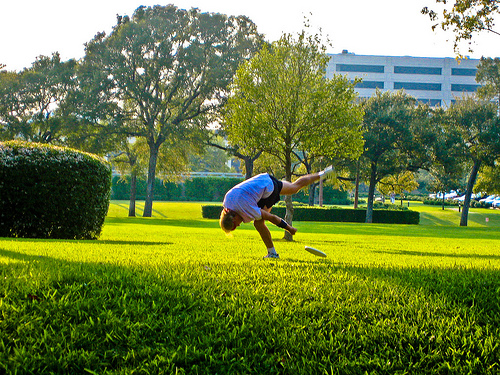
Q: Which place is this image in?
A: It is at the field.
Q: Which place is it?
A: It is a field.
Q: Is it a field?
A: Yes, it is a field.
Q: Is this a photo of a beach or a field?
A: It is showing a field.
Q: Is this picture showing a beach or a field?
A: It is showing a field.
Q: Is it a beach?
A: No, it is a field.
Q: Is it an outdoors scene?
A: Yes, it is outdoors.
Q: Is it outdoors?
A: Yes, it is outdoors.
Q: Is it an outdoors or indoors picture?
A: It is outdoors.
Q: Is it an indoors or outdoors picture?
A: It is outdoors.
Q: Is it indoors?
A: No, it is outdoors.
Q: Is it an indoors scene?
A: No, it is outdoors.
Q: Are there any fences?
A: No, there are no fences.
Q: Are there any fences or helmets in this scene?
A: No, there are no fences or helmets.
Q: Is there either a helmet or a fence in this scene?
A: No, there are no fences or helmets.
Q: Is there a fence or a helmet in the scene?
A: No, there are no fences or helmets.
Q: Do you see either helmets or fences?
A: No, there are no fences or helmets.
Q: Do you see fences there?
A: No, there are no fences.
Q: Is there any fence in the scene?
A: No, there are no fences.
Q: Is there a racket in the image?
A: No, there are no rackets.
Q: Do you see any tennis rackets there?
A: No, there are no tennis rackets.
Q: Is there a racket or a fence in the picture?
A: No, there are no rackets or fences.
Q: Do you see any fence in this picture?
A: No, there are no fences.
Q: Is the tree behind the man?
A: Yes, the tree is behind the man.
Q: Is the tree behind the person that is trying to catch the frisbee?
A: Yes, the tree is behind the man.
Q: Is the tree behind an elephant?
A: No, the tree is behind the man.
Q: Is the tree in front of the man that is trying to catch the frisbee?
A: No, the tree is behind the man.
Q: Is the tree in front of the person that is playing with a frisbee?
A: No, the tree is behind the man.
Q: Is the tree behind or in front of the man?
A: The tree is behind the man.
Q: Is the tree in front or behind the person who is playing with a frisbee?
A: The tree is behind the man.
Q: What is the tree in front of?
A: The tree is in front of the building.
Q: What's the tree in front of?
A: The tree is in front of the building.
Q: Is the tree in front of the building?
A: Yes, the tree is in front of the building.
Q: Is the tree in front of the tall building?
A: Yes, the tree is in front of the building.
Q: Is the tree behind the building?
A: No, the tree is in front of the building.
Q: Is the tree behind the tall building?
A: No, the tree is in front of the building.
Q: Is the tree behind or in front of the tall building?
A: The tree is in front of the building.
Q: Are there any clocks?
A: No, there are no clocks.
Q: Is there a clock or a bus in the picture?
A: No, there are no clocks or buses.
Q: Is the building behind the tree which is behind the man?
A: Yes, the building is behind the tree.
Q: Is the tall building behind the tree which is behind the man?
A: Yes, the building is behind the tree.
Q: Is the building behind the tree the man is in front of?
A: Yes, the building is behind the tree.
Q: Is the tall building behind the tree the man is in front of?
A: Yes, the building is behind the tree.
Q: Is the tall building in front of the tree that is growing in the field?
A: No, the building is behind the tree.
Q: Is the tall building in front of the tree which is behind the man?
A: No, the building is behind the tree.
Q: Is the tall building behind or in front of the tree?
A: The building is behind the tree.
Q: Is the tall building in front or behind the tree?
A: The building is behind the tree.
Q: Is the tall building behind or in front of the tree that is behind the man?
A: The building is behind the tree.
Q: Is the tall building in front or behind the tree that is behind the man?
A: The building is behind the tree.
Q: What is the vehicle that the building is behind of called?
A: The vehicle is a car.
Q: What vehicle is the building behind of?
A: The building is behind the car.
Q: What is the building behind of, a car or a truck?
A: The building is behind a car.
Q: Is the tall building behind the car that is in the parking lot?
A: Yes, the building is behind the car.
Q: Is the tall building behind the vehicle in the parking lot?
A: Yes, the building is behind the car.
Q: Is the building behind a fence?
A: No, the building is behind the car.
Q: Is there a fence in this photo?
A: No, there are no fences.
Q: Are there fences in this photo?
A: No, there are no fences.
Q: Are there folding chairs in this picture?
A: No, there are no folding chairs.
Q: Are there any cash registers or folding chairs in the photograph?
A: No, there are no folding chairs or cash registers.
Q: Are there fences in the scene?
A: No, there are no fences.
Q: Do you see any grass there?
A: Yes, there is grass.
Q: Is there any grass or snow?
A: Yes, there is grass.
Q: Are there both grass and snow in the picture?
A: No, there is grass but no snow.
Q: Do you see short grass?
A: Yes, there is short grass.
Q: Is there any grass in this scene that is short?
A: Yes, there is grass that is short.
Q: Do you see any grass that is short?
A: Yes, there is grass that is short.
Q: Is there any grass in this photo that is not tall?
A: Yes, there is short grass.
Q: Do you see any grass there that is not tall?
A: Yes, there is short grass.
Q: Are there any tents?
A: No, there are no tents.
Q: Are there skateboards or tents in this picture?
A: No, there are no tents or skateboards.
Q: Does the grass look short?
A: Yes, the grass is short.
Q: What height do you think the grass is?
A: The grass is short.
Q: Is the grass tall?
A: No, the grass is short.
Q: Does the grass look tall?
A: No, the grass is short.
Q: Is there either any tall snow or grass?
A: No, there is grass but it is short.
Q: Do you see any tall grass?
A: No, there is grass but it is short.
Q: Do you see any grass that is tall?
A: No, there is grass but it is short.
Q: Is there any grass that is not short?
A: No, there is grass but it is short.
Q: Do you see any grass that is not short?
A: No, there is grass but it is short.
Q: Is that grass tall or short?
A: The grass is short.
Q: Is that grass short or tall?
A: The grass is short.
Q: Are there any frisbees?
A: Yes, there is a frisbee.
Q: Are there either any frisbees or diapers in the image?
A: Yes, there is a frisbee.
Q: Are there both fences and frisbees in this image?
A: No, there is a frisbee but no fences.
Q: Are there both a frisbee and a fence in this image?
A: No, there is a frisbee but no fences.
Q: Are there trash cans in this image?
A: No, there are no trash cans.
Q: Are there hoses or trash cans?
A: No, there are no trash cans or hoses.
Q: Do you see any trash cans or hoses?
A: No, there are no trash cans or hoses.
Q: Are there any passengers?
A: No, there are no passengers.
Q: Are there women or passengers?
A: No, there are no passengers or women.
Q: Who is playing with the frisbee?
A: The man is playing with the frisbee.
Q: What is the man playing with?
A: The man is playing with a frisbee.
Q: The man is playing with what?
A: The man is playing with a frisbee.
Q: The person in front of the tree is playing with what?
A: The man is playing with a frisbee.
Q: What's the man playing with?
A: The man is playing with a frisbee.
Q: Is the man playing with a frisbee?
A: Yes, the man is playing with a frisbee.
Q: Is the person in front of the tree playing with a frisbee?
A: Yes, the man is playing with a frisbee.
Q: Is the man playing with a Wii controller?
A: No, the man is playing with a frisbee.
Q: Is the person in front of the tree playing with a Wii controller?
A: No, the man is playing with a frisbee.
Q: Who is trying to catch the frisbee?
A: The man is trying to catch the frisbee.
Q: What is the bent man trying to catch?
A: The man is trying to catch the frisbee.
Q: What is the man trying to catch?
A: The man is trying to catch the frisbee.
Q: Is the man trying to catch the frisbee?
A: Yes, the man is trying to catch the frisbee.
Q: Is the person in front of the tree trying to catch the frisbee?
A: Yes, the man is trying to catch the frisbee.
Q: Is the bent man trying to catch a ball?
A: No, the man is trying to catch the frisbee.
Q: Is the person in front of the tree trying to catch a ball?
A: No, the man is trying to catch the frisbee.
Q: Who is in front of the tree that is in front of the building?
A: The man is in front of the tree.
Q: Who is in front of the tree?
A: The man is in front of the tree.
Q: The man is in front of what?
A: The man is in front of the tree.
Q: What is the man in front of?
A: The man is in front of the tree.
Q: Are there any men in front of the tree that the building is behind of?
A: Yes, there is a man in front of the tree.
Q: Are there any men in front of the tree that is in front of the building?
A: Yes, there is a man in front of the tree.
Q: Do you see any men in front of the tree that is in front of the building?
A: Yes, there is a man in front of the tree.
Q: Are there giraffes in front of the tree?
A: No, there is a man in front of the tree.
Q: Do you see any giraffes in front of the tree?
A: No, there is a man in front of the tree.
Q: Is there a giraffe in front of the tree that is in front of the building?
A: No, there is a man in front of the tree.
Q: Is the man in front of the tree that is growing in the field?
A: Yes, the man is in front of the tree.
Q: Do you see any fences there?
A: No, there are no fences.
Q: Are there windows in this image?
A: Yes, there is a window.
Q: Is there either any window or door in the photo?
A: Yes, there is a window.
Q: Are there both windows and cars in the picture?
A: Yes, there are both a window and a car.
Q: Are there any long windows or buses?
A: Yes, there is a long window.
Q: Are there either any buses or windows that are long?
A: Yes, the window is long.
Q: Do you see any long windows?
A: Yes, there is a long window.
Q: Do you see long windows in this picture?
A: Yes, there is a long window.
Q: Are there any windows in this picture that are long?
A: Yes, there is a window that is long.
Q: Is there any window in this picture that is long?
A: Yes, there is a window that is long.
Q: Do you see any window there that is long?
A: Yes, there is a window that is long.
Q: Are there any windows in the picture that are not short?
A: Yes, there is a long window.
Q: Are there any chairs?
A: No, there are no chairs.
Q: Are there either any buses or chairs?
A: No, there are no chairs or buses.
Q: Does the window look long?
A: Yes, the window is long.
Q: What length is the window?
A: The window is long.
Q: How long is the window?
A: The window is long.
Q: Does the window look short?
A: No, the window is long.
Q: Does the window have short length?
A: No, the window is long.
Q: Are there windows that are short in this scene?
A: No, there is a window but it is long.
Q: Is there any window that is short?
A: No, there is a window but it is long.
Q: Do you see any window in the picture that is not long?
A: No, there is a window but it is long.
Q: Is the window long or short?
A: The window is long.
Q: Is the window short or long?
A: The window is long.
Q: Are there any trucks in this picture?
A: No, there are no trucks.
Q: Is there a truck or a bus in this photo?
A: No, there are no trucks or buses.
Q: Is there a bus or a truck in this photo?
A: No, there are no trucks or buses.